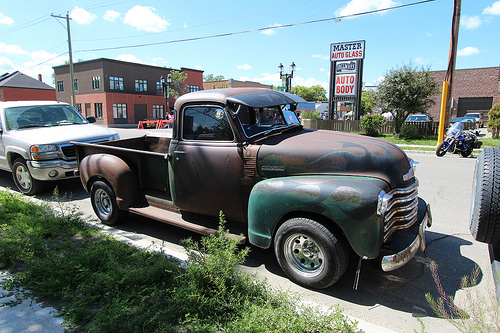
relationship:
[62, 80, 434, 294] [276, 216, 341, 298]
vehicle has wheel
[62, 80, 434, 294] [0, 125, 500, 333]
vehicle parked on road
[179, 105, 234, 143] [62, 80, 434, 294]
window on vehicle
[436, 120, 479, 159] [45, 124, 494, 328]
motorcycle on street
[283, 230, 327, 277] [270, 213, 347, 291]
spokes on wheel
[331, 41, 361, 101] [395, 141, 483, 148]
sign on sidewalk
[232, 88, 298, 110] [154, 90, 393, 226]
visor on truck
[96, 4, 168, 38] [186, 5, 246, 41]
clouds in sky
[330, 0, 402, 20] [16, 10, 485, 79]
cloud in sky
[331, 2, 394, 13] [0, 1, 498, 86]
cloud in sky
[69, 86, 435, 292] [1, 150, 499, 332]
vehicle on street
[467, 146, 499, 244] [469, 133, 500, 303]
tire on truck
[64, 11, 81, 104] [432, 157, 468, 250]
telephone pole across street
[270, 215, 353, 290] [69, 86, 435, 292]
wheel on old vehicle